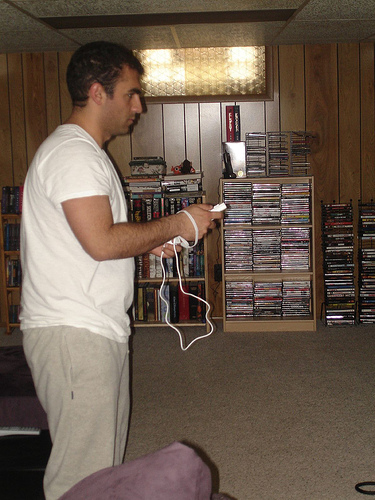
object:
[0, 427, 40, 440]
remote controller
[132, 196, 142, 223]
book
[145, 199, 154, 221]
book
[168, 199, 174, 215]
book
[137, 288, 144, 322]
book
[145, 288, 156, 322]
book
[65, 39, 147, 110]
hair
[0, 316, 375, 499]
carpet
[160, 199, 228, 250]
controller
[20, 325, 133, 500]
pants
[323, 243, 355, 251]
dvds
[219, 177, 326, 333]
case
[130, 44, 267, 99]
light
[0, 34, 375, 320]
wall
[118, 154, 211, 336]
bookshelf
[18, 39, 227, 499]
man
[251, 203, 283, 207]
dvds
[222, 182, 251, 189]
cds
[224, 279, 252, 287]
cds